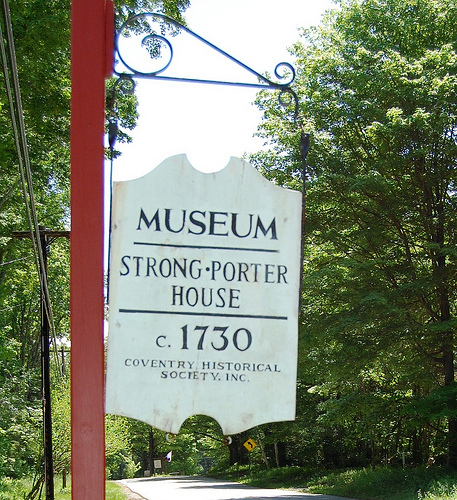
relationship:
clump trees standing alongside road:
[242, 0, 457, 470] [113, 471, 333, 498]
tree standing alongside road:
[124, 415, 172, 475] [113, 471, 333, 498]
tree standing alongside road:
[190, 430, 252, 475] [113, 471, 333, 498]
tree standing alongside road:
[34, 380, 131, 498] [113, 471, 333, 498]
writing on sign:
[122, 195, 289, 416] [102, 126, 325, 450]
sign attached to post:
[103, 154, 306, 437] [68, 0, 114, 498]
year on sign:
[142, 310, 271, 356] [84, 143, 307, 460]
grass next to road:
[168, 450, 341, 483] [114, 476, 350, 498]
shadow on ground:
[143, 455, 339, 496] [115, 468, 367, 496]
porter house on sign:
[169, 251, 291, 317] [110, 154, 305, 436]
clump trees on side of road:
[242, 0, 457, 470] [112, 474, 334, 498]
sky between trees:
[149, 88, 245, 137] [298, 25, 454, 493]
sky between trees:
[149, 88, 245, 137] [4, 3, 69, 497]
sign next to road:
[110, 154, 305, 436] [114, 476, 350, 497]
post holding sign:
[68, 4, 107, 498] [110, 154, 305, 436]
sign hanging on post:
[110, 154, 305, 436] [68, 0, 114, 498]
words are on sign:
[133, 206, 278, 241] [110, 154, 305, 436]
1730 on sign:
[179, 318, 255, 353] [110, 154, 305, 436]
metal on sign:
[108, 54, 318, 177] [110, 154, 305, 436]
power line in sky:
[0, 6, 69, 381] [110, 12, 294, 184]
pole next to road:
[25, 232, 56, 497] [113, 471, 333, 498]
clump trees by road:
[399, 50, 402, 125] [122, 475, 274, 498]